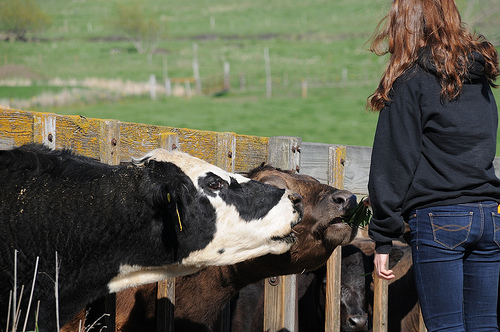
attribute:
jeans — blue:
[406, 197, 497, 331]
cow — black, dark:
[234, 245, 404, 330]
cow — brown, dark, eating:
[69, 167, 365, 327]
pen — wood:
[3, 108, 433, 327]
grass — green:
[2, 3, 499, 152]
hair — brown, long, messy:
[367, 0, 496, 111]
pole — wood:
[261, 253, 298, 331]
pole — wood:
[323, 242, 340, 330]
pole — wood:
[373, 245, 388, 330]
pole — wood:
[157, 276, 175, 331]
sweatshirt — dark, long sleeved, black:
[367, 47, 499, 259]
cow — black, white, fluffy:
[3, 142, 302, 329]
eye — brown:
[203, 176, 225, 193]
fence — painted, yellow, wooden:
[1, 106, 376, 198]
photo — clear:
[1, 2, 497, 330]